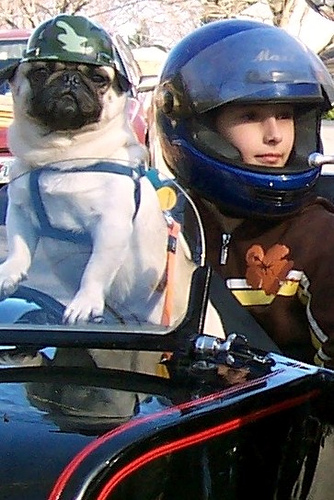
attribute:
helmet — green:
[11, 12, 128, 134]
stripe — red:
[110, 399, 260, 479]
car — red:
[0, 28, 154, 168]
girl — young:
[156, 30, 330, 365]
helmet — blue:
[155, 16, 332, 209]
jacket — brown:
[185, 190, 333, 365]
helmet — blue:
[225, 70, 251, 110]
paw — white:
[64, 284, 105, 325]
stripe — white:
[224, 268, 332, 365]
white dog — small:
[2, 14, 168, 333]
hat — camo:
[22, 13, 119, 70]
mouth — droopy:
[47, 86, 85, 122]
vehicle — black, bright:
[3, 158, 333, 498]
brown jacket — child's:
[205, 189, 331, 335]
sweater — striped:
[210, 209, 320, 340]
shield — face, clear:
[181, 23, 333, 123]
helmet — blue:
[147, 11, 332, 226]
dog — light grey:
[22, 57, 189, 308]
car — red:
[4, 29, 160, 177]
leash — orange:
[162, 220, 182, 326]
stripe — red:
[45, 376, 286, 497]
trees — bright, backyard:
[2, 9, 325, 20]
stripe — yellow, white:
[225, 271, 320, 349]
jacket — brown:
[197, 212, 323, 367]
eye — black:
[86, 70, 103, 82]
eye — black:
[30, 66, 49, 76]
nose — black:
[60, 69, 81, 89]